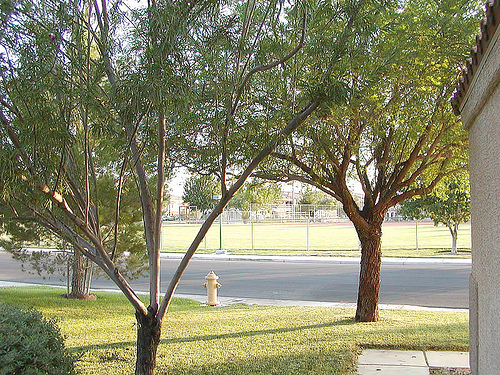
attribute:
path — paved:
[348, 338, 446, 373]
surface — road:
[129, 257, 453, 303]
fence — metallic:
[188, 219, 425, 254]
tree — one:
[268, 28, 473, 322]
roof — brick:
[440, 5, 498, 103]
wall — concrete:
[470, 107, 498, 371]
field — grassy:
[154, 297, 339, 373]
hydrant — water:
[200, 270, 220, 309]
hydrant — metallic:
[200, 270, 224, 306]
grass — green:
[174, 321, 315, 370]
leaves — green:
[337, 30, 419, 97]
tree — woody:
[334, 172, 415, 323]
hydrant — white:
[200, 273, 221, 308]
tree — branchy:
[32, 50, 280, 344]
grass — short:
[195, 311, 335, 365]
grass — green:
[201, 336, 323, 373]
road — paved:
[242, 265, 364, 297]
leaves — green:
[343, 39, 453, 125]